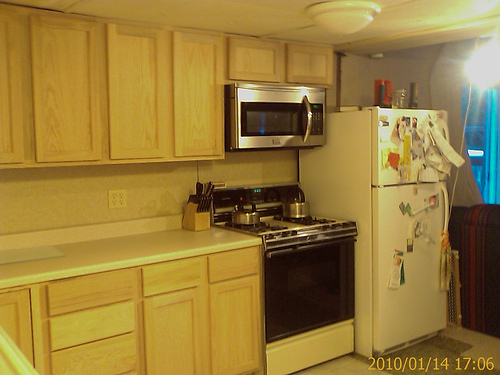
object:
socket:
[108, 189, 127, 209]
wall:
[0, 150, 302, 247]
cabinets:
[0, 2, 341, 375]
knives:
[187, 181, 216, 213]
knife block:
[181, 202, 211, 233]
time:
[253, 188, 262, 194]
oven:
[207, 183, 358, 375]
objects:
[376, 109, 466, 292]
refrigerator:
[297, 106, 451, 360]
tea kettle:
[232, 201, 260, 225]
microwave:
[225, 82, 329, 154]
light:
[446, 29, 499, 106]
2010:
[368, 356, 403, 371]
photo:
[0, 0, 499, 375]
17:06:
[456, 357, 495, 372]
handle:
[301, 95, 313, 142]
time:
[313, 104, 321, 109]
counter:
[0, 212, 268, 374]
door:
[262, 227, 357, 375]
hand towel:
[437, 233, 453, 293]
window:
[241, 102, 299, 137]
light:
[304, 1, 381, 38]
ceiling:
[1, 0, 500, 58]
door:
[370, 184, 452, 352]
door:
[373, 109, 448, 188]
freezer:
[299, 107, 450, 187]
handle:
[441, 185, 449, 236]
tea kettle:
[282, 185, 311, 218]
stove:
[208, 184, 358, 375]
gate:
[447, 247, 463, 330]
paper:
[387, 249, 406, 289]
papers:
[379, 110, 467, 184]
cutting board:
[0, 212, 259, 280]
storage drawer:
[261, 317, 354, 375]